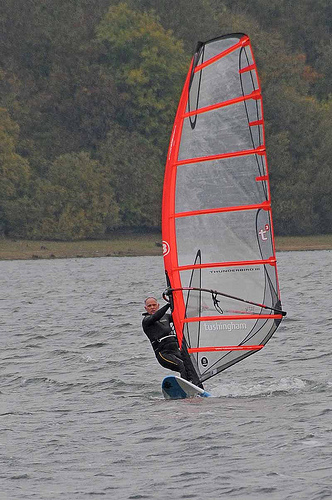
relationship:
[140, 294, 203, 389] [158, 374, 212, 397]
man of a surf board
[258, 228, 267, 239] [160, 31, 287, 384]
letter on sail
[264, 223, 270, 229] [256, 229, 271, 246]
3 above t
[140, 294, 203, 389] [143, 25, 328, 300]
man holding on sail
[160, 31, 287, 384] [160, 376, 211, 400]
sail on surf board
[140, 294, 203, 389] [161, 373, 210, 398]
man standing on panel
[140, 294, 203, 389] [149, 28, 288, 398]
man holding onto sail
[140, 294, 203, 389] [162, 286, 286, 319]
man holding onto bar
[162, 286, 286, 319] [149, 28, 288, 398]
bar on sail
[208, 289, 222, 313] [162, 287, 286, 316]
rope attached to black bar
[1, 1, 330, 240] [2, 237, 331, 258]
foliage along shore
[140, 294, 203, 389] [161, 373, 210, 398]
man on panel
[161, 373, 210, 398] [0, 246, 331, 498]
panel in choppy water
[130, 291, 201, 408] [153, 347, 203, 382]
man wearing pants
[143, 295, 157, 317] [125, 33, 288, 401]
face on windsurfer